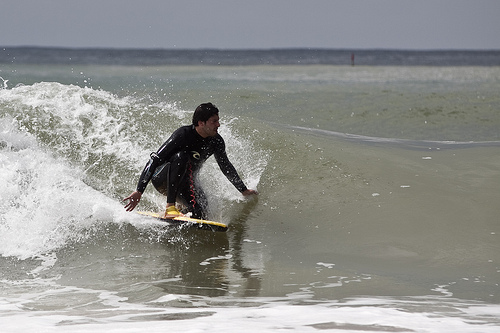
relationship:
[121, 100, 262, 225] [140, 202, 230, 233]
body kneeling on surfboard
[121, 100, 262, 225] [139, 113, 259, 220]
body has body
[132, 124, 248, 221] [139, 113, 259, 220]
black suit on body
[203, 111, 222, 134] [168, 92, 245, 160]
face on man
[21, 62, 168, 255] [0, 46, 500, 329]
wave in ocean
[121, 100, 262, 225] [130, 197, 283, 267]
body on surfboard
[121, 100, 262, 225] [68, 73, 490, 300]
body in water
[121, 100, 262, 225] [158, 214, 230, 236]
body on surfboard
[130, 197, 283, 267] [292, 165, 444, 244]
surfboard on water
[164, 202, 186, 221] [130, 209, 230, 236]
foot on surfboard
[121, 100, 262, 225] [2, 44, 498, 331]
body dragging water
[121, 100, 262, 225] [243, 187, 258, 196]
body has hand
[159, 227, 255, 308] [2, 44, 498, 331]
reflection in water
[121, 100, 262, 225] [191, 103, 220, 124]
body has black hair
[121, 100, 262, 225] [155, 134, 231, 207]
body wearing black suit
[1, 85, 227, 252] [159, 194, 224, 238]
water splashed by surfboard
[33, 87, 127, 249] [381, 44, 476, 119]
sea foam on ocean surface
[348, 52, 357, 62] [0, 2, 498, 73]
background person in background